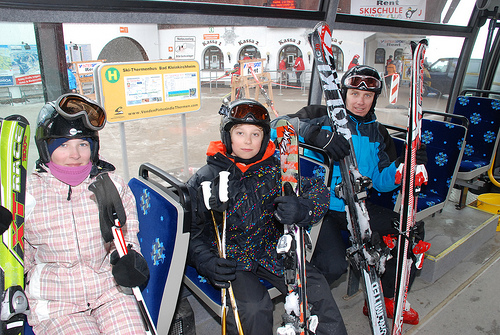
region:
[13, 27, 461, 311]
these people ae on the bus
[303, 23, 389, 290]
he is holding a black and white ski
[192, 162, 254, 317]
she holding ski poles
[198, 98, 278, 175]
this lady is wearing orange and black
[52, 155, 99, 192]
she is wearing a purple scarf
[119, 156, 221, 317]
she is sitting on a blue seat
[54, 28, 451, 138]
a window on the bus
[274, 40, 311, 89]
people in the background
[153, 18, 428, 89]
a center for paying fares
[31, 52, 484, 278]
this bus is transporting people to the slopes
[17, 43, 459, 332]
A group of skiers riding a bus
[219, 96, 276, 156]
The woman has a black helmet on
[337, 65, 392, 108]
A black helmet on the man's head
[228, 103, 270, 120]
A pair of red goggles on the black helmet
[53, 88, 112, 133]
The goggles are falling off of the helmet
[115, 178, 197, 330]
A blue bus seat under the woman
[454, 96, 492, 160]
A floral pattern on the blue bus seat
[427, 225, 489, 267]
A yellow line on the floor of the bus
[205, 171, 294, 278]
A black jacket on the female skier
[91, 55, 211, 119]
A large yellow sign outside of the bus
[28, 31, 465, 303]
skiers on a bus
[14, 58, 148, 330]
this lady is holding green skies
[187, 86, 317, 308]
this lady is wearing a black coat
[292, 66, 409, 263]
this man is wearing blue ski gear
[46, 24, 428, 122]
a staging area for skiers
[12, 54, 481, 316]
a bus that leads to the resort area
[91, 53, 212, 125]
a yellow sign in the background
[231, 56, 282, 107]
a sign in the background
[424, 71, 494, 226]
seats on the bus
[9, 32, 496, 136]
this area is busy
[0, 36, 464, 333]
people on a ski lift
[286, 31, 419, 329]
a man holding skies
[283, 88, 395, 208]
he is wearing a blue jacket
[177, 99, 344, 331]
a boy holding skies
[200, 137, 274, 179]
he has an orange hood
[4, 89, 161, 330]
a girl holding skies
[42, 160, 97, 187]
she has a purple scarf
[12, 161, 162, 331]
she has a pink plaid suit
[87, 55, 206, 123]
a sign outside the ski lift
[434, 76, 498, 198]
an empty chair in the ski lift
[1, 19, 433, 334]
The people sit on the seats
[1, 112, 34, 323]
The green skiis in the womens hand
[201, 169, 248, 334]
The skii poles in the womens hand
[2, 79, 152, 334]
The wome holds her skiis and poles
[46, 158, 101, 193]
The pink scarf arounf the womens neck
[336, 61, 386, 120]
The black helmet and orange googles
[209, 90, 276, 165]
The women weraing a helmet and googles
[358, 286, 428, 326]
The red boot of the man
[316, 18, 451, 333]
The man holding two pairs of skiis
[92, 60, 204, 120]
The yellow sign outside the window